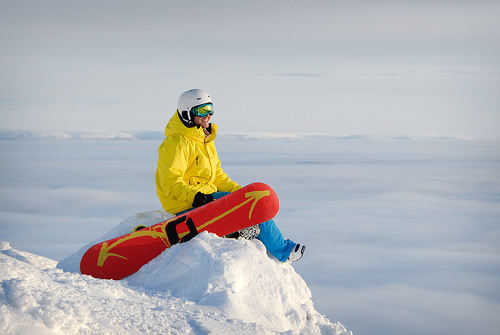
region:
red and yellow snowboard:
[76, 175, 283, 292]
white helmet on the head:
[160, 78, 228, 130]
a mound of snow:
[49, 198, 367, 333]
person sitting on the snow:
[131, 60, 340, 328]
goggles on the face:
[188, 100, 217, 120]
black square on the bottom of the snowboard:
[159, 210, 197, 246]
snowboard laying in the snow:
[63, 180, 290, 287]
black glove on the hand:
[189, 189, 213, 205]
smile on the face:
[196, 113, 214, 125]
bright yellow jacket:
[151, 111, 248, 208]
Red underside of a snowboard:
[81, 182, 280, 284]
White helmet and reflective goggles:
[176, 87, 213, 124]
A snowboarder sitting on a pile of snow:
[78, 88, 303, 281]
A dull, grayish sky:
[5, 3, 492, 138]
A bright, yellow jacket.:
[154, 111, 241, 212]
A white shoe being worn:
[280, 240, 307, 266]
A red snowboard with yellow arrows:
[80, 182, 280, 284]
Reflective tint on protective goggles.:
[192, 102, 214, 117]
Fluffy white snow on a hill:
[0, 240, 357, 334]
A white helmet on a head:
[177, 88, 214, 127]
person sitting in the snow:
[132, 68, 327, 293]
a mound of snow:
[62, 203, 347, 334]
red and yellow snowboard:
[78, 178, 282, 284]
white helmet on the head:
[173, 87, 215, 136]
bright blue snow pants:
[177, 184, 299, 263]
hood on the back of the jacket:
[159, 108, 184, 137]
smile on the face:
[200, 115, 214, 124]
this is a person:
[128, 69, 325, 288]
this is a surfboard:
[49, 172, 282, 282]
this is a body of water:
[46, 168, 112, 212]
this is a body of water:
[0, 112, 70, 180]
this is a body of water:
[372, 193, 424, 248]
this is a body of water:
[346, 252, 428, 321]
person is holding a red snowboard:
[78, 86, 307, 281]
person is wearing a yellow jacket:
[154, 87, 304, 262]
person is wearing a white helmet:
[156, 86, 304, 260]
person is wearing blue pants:
[155, 88, 307, 262]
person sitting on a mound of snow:
[54, 89, 353, 334]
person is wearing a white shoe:
[154, 86, 306, 264]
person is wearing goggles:
[157, 87, 305, 262]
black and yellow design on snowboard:
[80, 183, 281, 281]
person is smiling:
[155, 85, 307, 265]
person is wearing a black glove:
[155, 83, 306, 263]